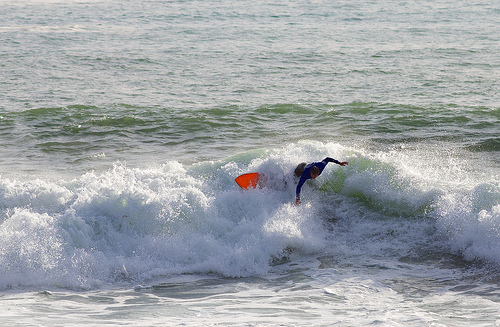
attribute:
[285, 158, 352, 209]
person — existing, falling, wearing wetsuit, surfing, facing downward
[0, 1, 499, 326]
ocean — existing, behind, blue, green, foamy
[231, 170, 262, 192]
surfboard — orange, red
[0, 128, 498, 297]
wave — big, crashing, white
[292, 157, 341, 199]
wetsuit — blue, black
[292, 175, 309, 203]
arm — stretched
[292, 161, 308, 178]
shorts — brown